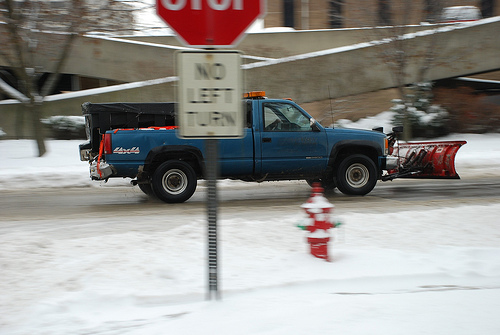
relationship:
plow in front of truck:
[385, 125, 468, 182] [286, 94, 393, 199]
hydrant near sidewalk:
[294, 180, 346, 265] [18, 266, 497, 334]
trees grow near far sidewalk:
[1, 2, 463, 155] [1, 169, 87, 192]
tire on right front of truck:
[336, 154, 379, 198] [286, 94, 393, 199]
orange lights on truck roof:
[244, 88, 293, 102] [239, 98, 296, 107]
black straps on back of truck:
[99, 102, 144, 125] [78, 92, 180, 204]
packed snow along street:
[1, 209, 500, 298] [1, 169, 498, 227]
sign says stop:
[153, 1, 267, 49] [159, 2, 250, 14]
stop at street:
[159, 2, 250, 14] [1, 169, 498, 227]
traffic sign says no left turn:
[176, 49, 246, 143] [183, 62, 236, 130]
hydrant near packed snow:
[294, 180, 346, 265] [1, 209, 500, 298]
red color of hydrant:
[307, 220, 331, 255] [294, 180, 346, 265]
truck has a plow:
[78, 89, 474, 204] [385, 125, 468, 182]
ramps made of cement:
[1, 16, 500, 141] [240, 25, 454, 93]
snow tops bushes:
[340, 110, 397, 132] [328, 94, 452, 139]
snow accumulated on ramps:
[22, 78, 174, 103] [1, 16, 500, 141]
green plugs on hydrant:
[295, 219, 344, 233] [294, 180, 346, 265]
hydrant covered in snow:
[294, 180, 346, 265] [298, 196, 335, 208]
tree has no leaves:
[1, 2, 160, 155] [1, 3, 158, 69]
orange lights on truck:
[244, 88, 293, 102] [78, 89, 474, 204]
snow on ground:
[1, 132, 499, 335] [0, 129, 499, 335]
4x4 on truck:
[113, 146, 142, 157] [78, 89, 474, 204]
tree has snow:
[1, 2, 160, 155] [0, 73, 28, 114]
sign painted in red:
[153, 1, 267, 49] [179, 15, 247, 50]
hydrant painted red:
[294, 180, 346, 265] [307, 220, 331, 255]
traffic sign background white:
[176, 49, 246, 143] [180, 55, 195, 84]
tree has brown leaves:
[1, 2, 160, 155] [0, 1, 114, 63]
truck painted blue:
[78, 89, 474, 204] [231, 140, 319, 173]